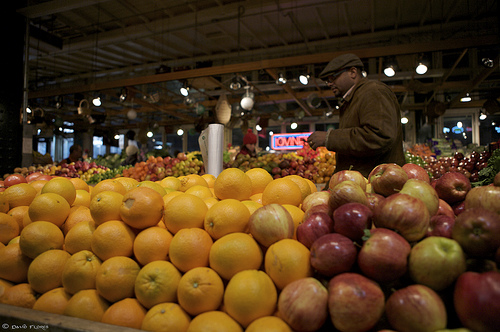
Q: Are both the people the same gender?
A: No, they are both male and female.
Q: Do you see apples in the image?
A: Yes, there is an apple.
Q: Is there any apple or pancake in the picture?
A: Yes, there is an apple.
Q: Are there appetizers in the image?
A: No, there are no appetizers.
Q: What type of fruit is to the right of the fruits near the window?
A: The fruit is an apple.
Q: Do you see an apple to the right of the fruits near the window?
A: Yes, there is an apple to the right of the fruits.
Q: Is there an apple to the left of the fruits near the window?
A: No, the apple is to the right of the fruits.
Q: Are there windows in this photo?
A: Yes, there is a window.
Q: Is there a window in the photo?
A: Yes, there is a window.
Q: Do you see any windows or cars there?
A: Yes, there is a window.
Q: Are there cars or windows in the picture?
A: Yes, there is a window.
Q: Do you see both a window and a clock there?
A: No, there is a window but no clocks.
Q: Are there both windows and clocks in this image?
A: No, there is a window but no clocks.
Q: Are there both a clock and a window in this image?
A: No, there is a window but no clocks.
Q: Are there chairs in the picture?
A: No, there are no chairs.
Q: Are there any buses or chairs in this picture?
A: No, there are no chairs or buses.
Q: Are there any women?
A: Yes, there is a woman.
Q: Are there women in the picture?
A: Yes, there is a woman.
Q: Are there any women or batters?
A: Yes, there is a woman.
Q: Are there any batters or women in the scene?
A: Yes, there is a woman.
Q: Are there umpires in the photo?
A: No, there are no umpires.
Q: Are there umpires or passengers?
A: No, there are no umpires or passengers.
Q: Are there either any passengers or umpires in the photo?
A: No, there are no umpires or passengers.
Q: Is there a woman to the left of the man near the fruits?
A: Yes, there is a woman to the left of the man.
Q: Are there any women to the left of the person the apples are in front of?
A: Yes, there is a woman to the left of the man.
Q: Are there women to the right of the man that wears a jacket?
A: No, the woman is to the left of the man.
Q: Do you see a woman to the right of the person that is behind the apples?
A: No, the woman is to the left of the man.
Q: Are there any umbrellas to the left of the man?
A: No, there is a woman to the left of the man.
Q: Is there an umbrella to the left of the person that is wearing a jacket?
A: No, there is a woman to the left of the man.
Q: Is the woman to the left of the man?
A: Yes, the woman is to the left of the man.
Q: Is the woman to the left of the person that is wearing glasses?
A: Yes, the woman is to the left of the man.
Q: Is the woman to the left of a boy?
A: No, the woman is to the left of the man.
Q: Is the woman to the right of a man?
A: No, the woman is to the left of a man.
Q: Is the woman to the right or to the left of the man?
A: The woman is to the left of the man.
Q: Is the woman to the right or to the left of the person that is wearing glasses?
A: The woman is to the left of the man.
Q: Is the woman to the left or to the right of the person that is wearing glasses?
A: The woman is to the left of the man.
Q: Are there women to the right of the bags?
A: Yes, there is a woman to the right of the bags.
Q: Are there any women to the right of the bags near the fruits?
A: Yes, there is a woman to the right of the bags.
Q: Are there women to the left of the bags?
A: No, the woman is to the right of the bags.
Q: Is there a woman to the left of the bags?
A: No, the woman is to the right of the bags.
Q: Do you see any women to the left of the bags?
A: No, the woman is to the right of the bags.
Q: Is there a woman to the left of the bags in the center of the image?
A: No, the woman is to the right of the bags.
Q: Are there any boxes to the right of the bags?
A: No, there is a woman to the right of the bags.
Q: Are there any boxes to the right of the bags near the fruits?
A: No, there is a woman to the right of the bags.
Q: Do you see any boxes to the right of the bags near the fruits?
A: No, there is a woman to the right of the bags.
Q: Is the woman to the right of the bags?
A: Yes, the woman is to the right of the bags.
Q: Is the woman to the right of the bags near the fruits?
A: Yes, the woman is to the right of the bags.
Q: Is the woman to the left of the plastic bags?
A: No, the woman is to the right of the bags.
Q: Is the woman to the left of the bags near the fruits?
A: No, the woman is to the right of the bags.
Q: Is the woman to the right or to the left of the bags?
A: The woman is to the right of the bags.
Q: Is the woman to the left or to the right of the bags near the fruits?
A: The woman is to the right of the bags.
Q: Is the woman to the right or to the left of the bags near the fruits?
A: The woman is to the right of the bags.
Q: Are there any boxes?
A: No, there are no boxes.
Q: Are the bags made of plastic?
A: Yes, the bags are made of plastic.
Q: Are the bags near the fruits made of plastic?
A: Yes, the bags are made of plastic.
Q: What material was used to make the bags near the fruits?
A: The bags are made of plastic.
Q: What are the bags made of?
A: The bags are made of plastic.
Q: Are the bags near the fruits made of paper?
A: No, the bags are made of plastic.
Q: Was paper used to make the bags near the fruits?
A: No, the bags are made of plastic.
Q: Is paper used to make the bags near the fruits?
A: No, the bags are made of plastic.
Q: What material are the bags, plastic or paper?
A: The bags are made of plastic.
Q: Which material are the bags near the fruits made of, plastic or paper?
A: The bags are made of plastic.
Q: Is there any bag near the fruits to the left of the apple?
A: Yes, there are bags near the fruits.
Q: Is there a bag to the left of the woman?
A: Yes, there are bags to the left of the woman.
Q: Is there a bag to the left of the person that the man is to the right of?
A: Yes, there are bags to the left of the woman.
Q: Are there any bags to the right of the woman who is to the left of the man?
A: No, the bags are to the left of the woman.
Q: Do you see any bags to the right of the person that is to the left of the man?
A: No, the bags are to the left of the woman.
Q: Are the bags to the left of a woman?
A: Yes, the bags are to the left of a woman.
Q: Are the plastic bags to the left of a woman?
A: Yes, the bags are to the left of a woman.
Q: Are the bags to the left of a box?
A: No, the bags are to the left of a woman.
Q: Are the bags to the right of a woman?
A: No, the bags are to the left of a woman.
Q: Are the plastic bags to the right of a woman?
A: No, the bags are to the left of a woman.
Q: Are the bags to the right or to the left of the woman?
A: The bags are to the left of the woman.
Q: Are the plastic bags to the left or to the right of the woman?
A: The bags are to the left of the woman.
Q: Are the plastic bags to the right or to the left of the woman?
A: The bags are to the left of the woman.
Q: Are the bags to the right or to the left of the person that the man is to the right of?
A: The bags are to the left of the woman.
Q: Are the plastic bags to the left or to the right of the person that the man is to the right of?
A: The bags are to the left of the woman.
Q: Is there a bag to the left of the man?
A: Yes, there are bags to the left of the man.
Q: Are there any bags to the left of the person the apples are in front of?
A: Yes, there are bags to the left of the man.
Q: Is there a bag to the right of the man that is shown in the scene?
A: No, the bags are to the left of the man.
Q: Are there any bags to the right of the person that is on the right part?
A: No, the bags are to the left of the man.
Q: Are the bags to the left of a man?
A: Yes, the bags are to the left of a man.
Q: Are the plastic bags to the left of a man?
A: Yes, the bags are to the left of a man.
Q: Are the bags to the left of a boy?
A: No, the bags are to the left of a man.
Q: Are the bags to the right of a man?
A: No, the bags are to the left of a man.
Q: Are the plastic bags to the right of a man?
A: No, the bags are to the left of a man.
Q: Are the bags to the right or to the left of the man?
A: The bags are to the left of the man.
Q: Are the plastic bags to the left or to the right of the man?
A: The bags are to the left of the man.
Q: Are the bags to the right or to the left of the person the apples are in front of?
A: The bags are to the left of the man.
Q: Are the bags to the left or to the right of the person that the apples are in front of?
A: The bags are to the left of the man.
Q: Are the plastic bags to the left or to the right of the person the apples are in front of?
A: The bags are to the left of the man.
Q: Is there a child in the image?
A: No, there are no children.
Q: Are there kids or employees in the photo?
A: No, there are no kids or employees.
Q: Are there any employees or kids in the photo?
A: No, there are no kids or employees.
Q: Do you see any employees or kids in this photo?
A: No, there are no kids or employees.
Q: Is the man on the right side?
A: Yes, the man is on the right of the image.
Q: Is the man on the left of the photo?
A: No, the man is on the right of the image.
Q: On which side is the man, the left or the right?
A: The man is on the right of the image.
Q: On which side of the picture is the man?
A: The man is on the right of the image.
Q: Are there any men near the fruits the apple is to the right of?
A: Yes, there is a man near the fruits.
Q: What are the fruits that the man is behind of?
A: The fruits are apples.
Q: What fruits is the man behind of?
A: The man is behind the apples.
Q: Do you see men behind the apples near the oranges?
A: Yes, there is a man behind the apples.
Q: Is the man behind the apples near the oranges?
A: Yes, the man is behind the apples.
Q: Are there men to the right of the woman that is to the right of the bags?
A: Yes, there is a man to the right of the woman.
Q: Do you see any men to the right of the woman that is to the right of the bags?
A: Yes, there is a man to the right of the woman.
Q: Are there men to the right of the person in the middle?
A: Yes, there is a man to the right of the woman.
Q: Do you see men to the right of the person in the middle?
A: Yes, there is a man to the right of the woman.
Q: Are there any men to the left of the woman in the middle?
A: No, the man is to the right of the woman.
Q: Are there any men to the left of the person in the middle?
A: No, the man is to the right of the woman.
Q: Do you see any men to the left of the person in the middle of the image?
A: No, the man is to the right of the woman.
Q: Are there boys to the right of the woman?
A: No, there is a man to the right of the woman.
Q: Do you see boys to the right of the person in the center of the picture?
A: No, there is a man to the right of the woman.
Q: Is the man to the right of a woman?
A: Yes, the man is to the right of a woman.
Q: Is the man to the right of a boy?
A: No, the man is to the right of a woman.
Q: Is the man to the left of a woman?
A: No, the man is to the right of a woman.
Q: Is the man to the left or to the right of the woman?
A: The man is to the right of the woman.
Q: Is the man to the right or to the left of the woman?
A: The man is to the right of the woman.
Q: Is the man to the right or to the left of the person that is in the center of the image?
A: The man is to the right of the woman.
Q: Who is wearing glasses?
A: The man is wearing glasses.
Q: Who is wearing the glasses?
A: The man is wearing glasses.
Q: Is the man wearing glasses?
A: Yes, the man is wearing glasses.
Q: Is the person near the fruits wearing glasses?
A: Yes, the man is wearing glasses.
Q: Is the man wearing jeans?
A: No, the man is wearing glasses.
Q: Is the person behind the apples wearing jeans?
A: No, the man is wearing glasses.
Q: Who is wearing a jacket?
A: The man is wearing a jacket.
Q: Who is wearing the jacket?
A: The man is wearing a jacket.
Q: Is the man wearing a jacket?
A: Yes, the man is wearing a jacket.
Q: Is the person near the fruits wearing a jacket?
A: Yes, the man is wearing a jacket.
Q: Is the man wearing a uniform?
A: No, the man is wearing a jacket.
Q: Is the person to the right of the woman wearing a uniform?
A: No, the man is wearing a jacket.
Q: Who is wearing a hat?
A: The man is wearing a hat.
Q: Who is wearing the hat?
A: The man is wearing a hat.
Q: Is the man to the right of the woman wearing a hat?
A: Yes, the man is wearing a hat.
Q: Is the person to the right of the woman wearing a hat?
A: Yes, the man is wearing a hat.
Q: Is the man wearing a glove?
A: No, the man is wearing a hat.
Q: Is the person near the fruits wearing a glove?
A: No, the man is wearing a hat.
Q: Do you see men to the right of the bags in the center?
A: Yes, there is a man to the right of the bags.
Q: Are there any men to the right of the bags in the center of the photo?
A: Yes, there is a man to the right of the bags.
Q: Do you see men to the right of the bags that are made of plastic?
A: Yes, there is a man to the right of the bags.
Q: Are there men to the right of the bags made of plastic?
A: Yes, there is a man to the right of the bags.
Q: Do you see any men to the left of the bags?
A: No, the man is to the right of the bags.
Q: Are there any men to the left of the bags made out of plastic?
A: No, the man is to the right of the bags.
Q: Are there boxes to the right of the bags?
A: No, there is a man to the right of the bags.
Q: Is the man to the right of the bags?
A: Yes, the man is to the right of the bags.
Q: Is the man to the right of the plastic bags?
A: Yes, the man is to the right of the bags.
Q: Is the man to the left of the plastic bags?
A: No, the man is to the right of the bags.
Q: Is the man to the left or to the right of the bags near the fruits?
A: The man is to the right of the bags.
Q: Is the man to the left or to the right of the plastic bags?
A: The man is to the right of the bags.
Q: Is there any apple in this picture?
A: Yes, there are apples.